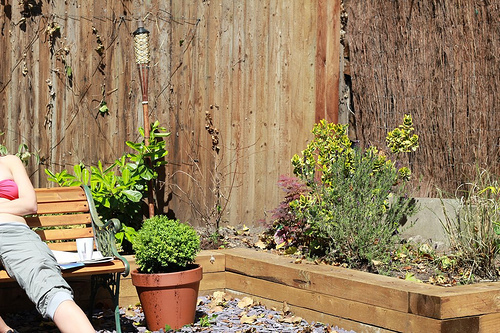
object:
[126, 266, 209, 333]
pot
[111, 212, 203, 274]
plant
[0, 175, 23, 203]
top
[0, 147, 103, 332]
woman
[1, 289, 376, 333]
gravel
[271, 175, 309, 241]
purple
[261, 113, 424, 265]
bush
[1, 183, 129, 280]
wood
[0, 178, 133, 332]
bench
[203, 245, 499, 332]
wooden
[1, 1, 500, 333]
picture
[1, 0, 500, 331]
day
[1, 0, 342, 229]
fence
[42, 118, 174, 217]
planters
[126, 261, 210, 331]
planter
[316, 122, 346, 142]
yellow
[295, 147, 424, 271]
plant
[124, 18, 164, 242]
torch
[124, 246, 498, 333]
box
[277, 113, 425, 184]
flowers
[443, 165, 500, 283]
plants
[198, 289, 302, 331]
leaves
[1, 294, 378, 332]
ground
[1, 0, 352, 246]
wooden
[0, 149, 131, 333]
half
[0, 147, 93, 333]
person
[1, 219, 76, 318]
pants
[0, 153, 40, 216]
arm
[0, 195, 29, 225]
stomach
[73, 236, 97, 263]
cup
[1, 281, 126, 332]
shadow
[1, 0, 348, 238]
front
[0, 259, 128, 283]
edge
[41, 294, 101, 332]
calf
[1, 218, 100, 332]
leg